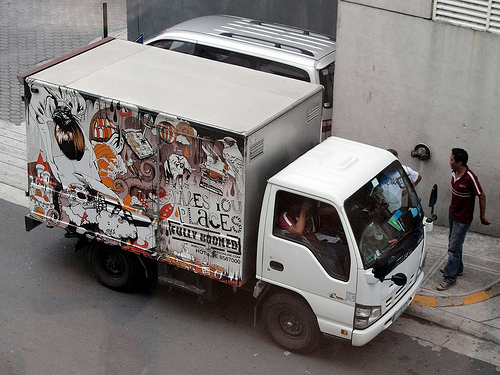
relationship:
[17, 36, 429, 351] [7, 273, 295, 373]
delivery truck on road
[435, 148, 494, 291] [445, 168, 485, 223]
man wearing red shirt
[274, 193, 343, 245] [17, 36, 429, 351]
man inside delivery truck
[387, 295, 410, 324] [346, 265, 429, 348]
plate on bumper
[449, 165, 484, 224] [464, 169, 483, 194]
red shirt with stripe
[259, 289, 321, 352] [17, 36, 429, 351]
front tire of delivery truck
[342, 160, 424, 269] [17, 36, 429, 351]
window of delivery truck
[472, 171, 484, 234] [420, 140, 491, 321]
arm of man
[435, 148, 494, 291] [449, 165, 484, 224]
man wearing red shirt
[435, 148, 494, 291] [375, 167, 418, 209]
man wearing shirt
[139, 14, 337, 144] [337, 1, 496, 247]
van near wall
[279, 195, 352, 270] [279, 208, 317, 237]
man wearing shirt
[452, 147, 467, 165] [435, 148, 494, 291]
black hair of man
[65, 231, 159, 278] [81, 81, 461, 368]
tire of truck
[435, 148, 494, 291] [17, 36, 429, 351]
man sitting in delivery truck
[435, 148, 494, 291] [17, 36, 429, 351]
man standing outside by delivery truck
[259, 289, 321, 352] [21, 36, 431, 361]
front tire on a delivery truck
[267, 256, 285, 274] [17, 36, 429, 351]
door handle on a delivery truck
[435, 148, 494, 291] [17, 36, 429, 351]
man standing by delivery truck